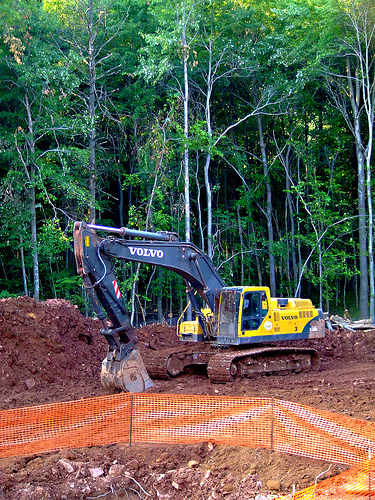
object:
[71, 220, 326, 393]
volvo tractor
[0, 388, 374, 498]
fence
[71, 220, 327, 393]
tractor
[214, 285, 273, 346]
cab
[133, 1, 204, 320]
tree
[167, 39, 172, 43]
leaf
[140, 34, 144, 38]
leaf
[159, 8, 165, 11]
leaf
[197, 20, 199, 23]
leaf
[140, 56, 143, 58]
leaf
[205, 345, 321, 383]
tread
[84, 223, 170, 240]
hydraulic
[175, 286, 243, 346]
front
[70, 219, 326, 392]
backhoe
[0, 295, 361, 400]
dirt pile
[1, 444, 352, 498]
hole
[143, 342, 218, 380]
track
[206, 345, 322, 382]
track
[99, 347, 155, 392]
bucket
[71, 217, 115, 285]
hydraulic hose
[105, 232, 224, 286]
hydraulic hose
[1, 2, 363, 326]
stand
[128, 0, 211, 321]
tree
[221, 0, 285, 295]
tree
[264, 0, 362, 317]
tree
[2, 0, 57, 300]
tree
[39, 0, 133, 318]
tree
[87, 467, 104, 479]
rock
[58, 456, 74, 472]
rock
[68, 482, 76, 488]
rock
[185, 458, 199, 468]
rock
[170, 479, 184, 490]
rock